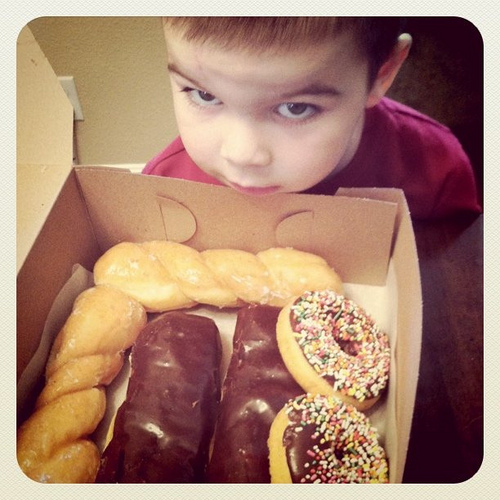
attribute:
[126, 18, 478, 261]
child — young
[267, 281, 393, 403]
donut — chocolate sprinkled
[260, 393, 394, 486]
dougnut — chocolate sprinkled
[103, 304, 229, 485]
donut — large, chocolate, glazed, long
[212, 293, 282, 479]
doughnut — long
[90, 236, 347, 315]
pastry — rope like, sugar glazed, twist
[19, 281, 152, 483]
dougnut — twist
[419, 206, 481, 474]
table — brown, dark brown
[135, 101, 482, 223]
shirt — red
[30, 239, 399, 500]
donuts — twisty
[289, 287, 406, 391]
sprinkles — multicolored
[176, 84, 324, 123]
eyes — gray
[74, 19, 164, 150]
wall — beige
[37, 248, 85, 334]
paper — white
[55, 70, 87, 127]
outlet — white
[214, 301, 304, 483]
eclair — chocolate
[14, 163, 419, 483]
box — cardboard, foldable, brown